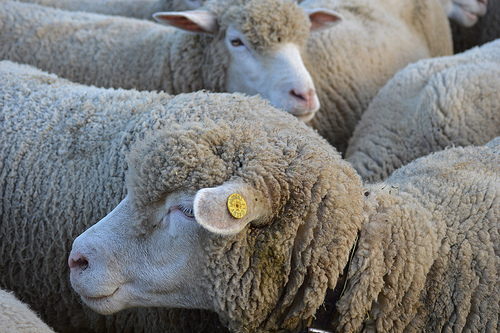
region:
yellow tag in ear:
[226, 191, 250, 219]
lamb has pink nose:
[287, 83, 319, 110]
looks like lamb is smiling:
[67, 232, 150, 322]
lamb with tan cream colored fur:
[68, 121, 498, 324]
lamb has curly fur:
[8, 69, 98, 211]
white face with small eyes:
[218, 23, 318, 125]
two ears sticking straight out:
[145, 4, 347, 37]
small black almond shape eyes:
[223, 34, 251, 56]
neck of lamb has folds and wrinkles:
[278, 172, 435, 327]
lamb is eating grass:
[337, 39, 499, 189]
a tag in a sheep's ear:
[229, 193, 251, 226]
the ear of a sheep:
[154, 6, 226, 33]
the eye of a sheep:
[229, 32, 243, 46]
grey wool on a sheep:
[23, 123, 98, 188]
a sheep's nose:
[287, 79, 317, 104]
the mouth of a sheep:
[73, 287, 128, 309]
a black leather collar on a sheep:
[326, 226, 351, 330]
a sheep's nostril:
[71, 255, 93, 267]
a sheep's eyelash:
[180, 200, 190, 210]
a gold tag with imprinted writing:
[223, 190, 250, 218]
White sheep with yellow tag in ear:
[45, 106, 499, 331]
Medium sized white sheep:
[2, 0, 347, 116]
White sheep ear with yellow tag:
[182, 158, 287, 250]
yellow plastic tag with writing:
[220, 182, 252, 222]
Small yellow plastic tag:
[215, 186, 256, 222]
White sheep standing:
[0, 4, 345, 124]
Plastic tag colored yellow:
[222, 186, 249, 226]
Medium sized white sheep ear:
[146, 5, 221, 40]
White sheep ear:
[290, 5, 352, 36]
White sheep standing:
[53, 113, 498, 331]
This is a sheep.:
[54, 110, 499, 331]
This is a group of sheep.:
[6, 3, 490, 328]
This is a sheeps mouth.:
[59, 223, 156, 319]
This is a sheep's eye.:
[151, 197, 210, 227]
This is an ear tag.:
[213, 176, 264, 224]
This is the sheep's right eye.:
[223, 31, 254, 60]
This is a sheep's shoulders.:
[351, 43, 482, 200]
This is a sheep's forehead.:
[137, 114, 331, 224]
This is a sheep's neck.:
[261, 167, 371, 331]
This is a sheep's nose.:
[56, 233, 101, 270]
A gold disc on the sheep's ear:
[224, 189, 252, 224]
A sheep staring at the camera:
[0, 0, 341, 122]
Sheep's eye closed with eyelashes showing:
[171, 194, 198, 226]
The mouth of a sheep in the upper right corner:
[444, 0, 499, 27]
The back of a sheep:
[341, 37, 498, 177]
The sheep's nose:
[284, 84, 321, 111]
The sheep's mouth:
[78, 274, 135, 311]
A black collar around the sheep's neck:
[310, 225, 363, 332]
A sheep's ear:
[149, 5, 220, 35]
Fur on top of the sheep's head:
[228, 0, 309, 51]